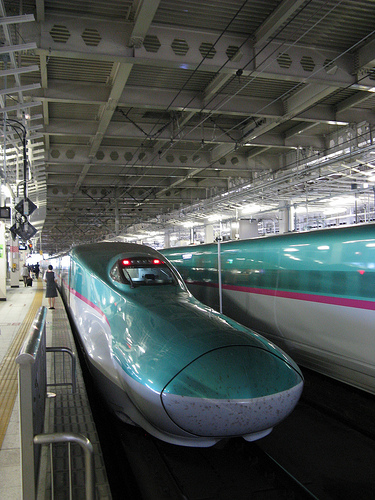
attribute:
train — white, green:
[67, 232, 318, 453]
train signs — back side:
[13, 182, 37, 245]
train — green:
[159, 222, 373, 374]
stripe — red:
[191, 272, 373, 315]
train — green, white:
[42, 243, 315, 461]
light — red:
[154, 258, 160, 264]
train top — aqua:
[69, 240, 309, 399]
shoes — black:
[34, 295, 82, 331]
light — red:
[122, 260, 131, 265]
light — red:
[120, 257, 130, 266]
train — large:
[37, 240, 305, 448]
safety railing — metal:
[17, 307, 95, 492]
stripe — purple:
[289, 282, 374, 327]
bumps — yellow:
[1, 283, 43, 407]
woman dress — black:
[33, 266, 62, 315]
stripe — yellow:
[197, 232, 233, 316]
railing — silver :
[32, 311, 81, 472]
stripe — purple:
[211, 282, 371, 313]